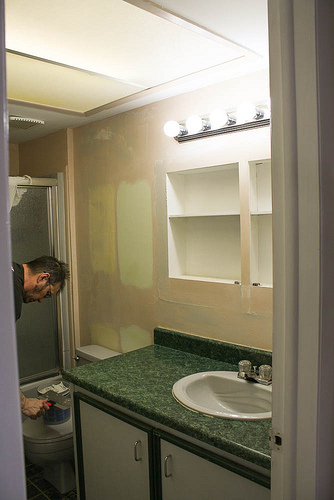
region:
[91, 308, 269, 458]
The countertop is green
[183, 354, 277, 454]
The sink is white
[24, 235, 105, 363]
There is a man in the bathroom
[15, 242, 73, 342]
The man is wearing glasses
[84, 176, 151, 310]
The wall is bare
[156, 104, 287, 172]
There are lights on the wall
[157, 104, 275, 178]
The lights are on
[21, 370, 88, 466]
There is paint on the toilet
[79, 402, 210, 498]
The cupboards are white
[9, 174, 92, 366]
The man is next to the shower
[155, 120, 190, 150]
white silver light in bathroom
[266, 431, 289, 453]
small hole in bathroom door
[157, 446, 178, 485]
silver handle on bathroom cabinet door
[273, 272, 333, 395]
white door bathroom frame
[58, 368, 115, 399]
edge of green counter tile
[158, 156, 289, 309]
white bathroom cabinet with shelves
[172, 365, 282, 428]
white porcelain bathroom sink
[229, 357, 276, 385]
silver bathroom faucet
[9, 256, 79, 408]
man bending over white bathroom bowl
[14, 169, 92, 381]
white clear glass in bathroom shower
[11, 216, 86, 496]
Man is fixing something over toilet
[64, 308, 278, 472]
Bathroom counter top is green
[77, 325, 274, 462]
Counter top is made of granite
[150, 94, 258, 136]
Lights of bathroom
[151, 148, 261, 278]
Shelf is built-in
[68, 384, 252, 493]
Cabinets are white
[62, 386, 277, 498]
Cabinet border is black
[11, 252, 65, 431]
Man wears glasses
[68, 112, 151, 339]
Wall is faded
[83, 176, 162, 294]
Wall has stains of paint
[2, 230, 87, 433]
Man is working inside bathroom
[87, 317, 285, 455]
Bathroom sink counter is green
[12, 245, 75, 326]
Man has dark colored hair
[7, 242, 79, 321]
Man is wearing eyeglasses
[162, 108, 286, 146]
Bathroom lights are on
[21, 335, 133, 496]
White bathroom toilet is in view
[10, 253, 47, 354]
Man is wearing a dark shirt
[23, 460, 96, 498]
Bathroom floor is dark tiles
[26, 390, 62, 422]
Man's hand is holding a object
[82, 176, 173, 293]
Two different colors of paint are on the wall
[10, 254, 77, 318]
Man wearing glasses looking down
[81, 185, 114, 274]
Yellow paint on the wall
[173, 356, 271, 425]
White round sink in a vanity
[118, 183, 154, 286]
Light colored paint on the wall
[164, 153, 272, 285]
A medicine cabinet without doors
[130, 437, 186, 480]
Two handles on the vanity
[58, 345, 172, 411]
Green counter top of the vanity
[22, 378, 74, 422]
A man's hand using a tool to work on the bathroom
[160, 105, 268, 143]
Lights on the wall above the medicine cabinet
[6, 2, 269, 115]
The lighted ceiling